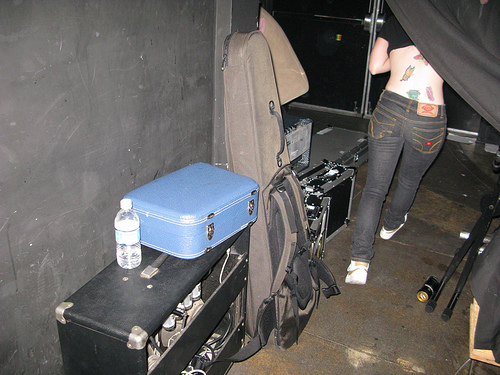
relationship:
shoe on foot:
[344, 258, 368, 287] [345, 259, 370, 286]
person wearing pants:
[340, 9, 449, 285] [347, 86, 450, 265]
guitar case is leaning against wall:
[218, 31, 335, 364] [2, 1, 268, 371]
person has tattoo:
[326, 14, 498, 227] [427, 86, 434, 98]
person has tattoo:
[326, 14, 498, 227] [407, 88, 421, 100]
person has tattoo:
[326, 14, 498, 227] [400, 65, 416, 83]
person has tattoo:
[326, 14, 498, 227] [413, 53, 431, 66]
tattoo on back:
[427, 86, 434, 98] [373, 9, 445, 115]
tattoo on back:
[407, 88, 421, 100] [373, 9, 445, 115]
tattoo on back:
[400, 65, 416, 83] [373, 9, 445, 115]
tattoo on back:
[413, 53, 431, 66] [373, 9, 445, 115]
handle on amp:
[141, 252, 170, 278] [86, 246, 303, 371]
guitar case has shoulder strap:
[218, 31, 340, 364] [271, 191, 297, 295]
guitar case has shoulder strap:
[218, 31, 340, 364] [281, 172, 311, 249]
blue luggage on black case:
[122, 161, 258, 258] [53, 219, 248, 371]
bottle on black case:
[114, 198, 143, 269] [53, 219, 248, 371]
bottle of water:
[114, 198, 143, 269] [114, 214, 143, 267]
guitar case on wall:
[218, 31, 335, 364] [2, 1, 268, 371]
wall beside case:
[0, 0, 215, 374] [52, 196, 251, 373]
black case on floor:
[54, 226, 250, 375] [225, 104, 496, 373]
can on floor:
[406, 261, 476, 319] [225, 104, 496, 373]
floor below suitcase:
[220, 104, 495, 373] [102, 165, 432, 357]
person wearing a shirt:
[340, 9, 449, 285] [373, 23, 418, 52]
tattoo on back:
[400, 65, 416, 83] [386, 28, 442, 104]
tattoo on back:
[426, 86, 435, 100] [386, 28, 442, 104]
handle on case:
[261, 93, 292, 177] [210, 28, 325, 343]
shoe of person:
[344, 260, 371, 285] [340, 13, 451, 284]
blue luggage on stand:
[118, 161, 260, 260] [53, 222, 247, 374]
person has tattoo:
[340, 9, 449, 285] [412, 49, 431, 68]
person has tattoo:
[340, 9, 449, 285] [396, 62, 419, 82]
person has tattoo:
[340, 9, 449, 285] [407, 88, 421, 100]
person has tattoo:
[340, 9, 449, 285] [426, 86, 435, 100]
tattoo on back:
[412, 49, 431, 68] [382, 32, 446, 109]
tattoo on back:
[396, 62, 419, 82] [382, 32, 446, 109]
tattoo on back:
[407, 88, 421, 100] [382, 32, 446, 109]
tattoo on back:
[426, 86, 435, 100] [382, 32, 446, 109]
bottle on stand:
[88, 196, 155, 272] [61, 235, 251, 372]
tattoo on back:
[413, 53, 431, 66] [376, 49, 474, 142]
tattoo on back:
[426, 86, 435, 100] [376, 49, 474, 142]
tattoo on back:
[407, 88, 421, 101] [376, 49, 474, 142]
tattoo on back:
[400, 65, 416, 83] [384, 29, 448, 110]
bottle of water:
[114, 198, 143, 269] [120, 247, 137, 264]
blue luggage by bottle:
[118, 161, 260, 260] [109, 186, 144, 271]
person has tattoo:
[340, 9, 449, 285] [423, 82, 435, 104]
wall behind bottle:
[0, 2, 258, 374] [111, 196, 143, 271]